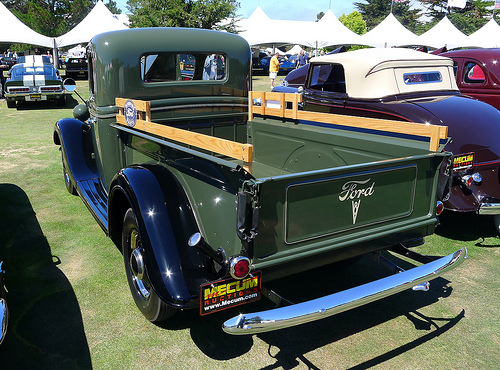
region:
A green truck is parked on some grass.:
[47, 18, 477, 360]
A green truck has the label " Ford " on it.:
[312, 161, 392, 232]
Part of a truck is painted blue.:
[40, 107, 230, 332]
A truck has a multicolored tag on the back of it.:
[186, 265, 266, 323]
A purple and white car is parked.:
[260, 35, 499, 241]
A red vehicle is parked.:
[427, 40, 498, 125]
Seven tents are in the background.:
[0, 0, 499, 92]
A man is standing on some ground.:
[257, 41, 282, 91]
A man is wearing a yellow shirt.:
[261, 47, 286, 77]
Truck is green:
[44, 18, 469, 356]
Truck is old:
[46, 16, 471, 349]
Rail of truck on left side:
[110, 93, 260, 171]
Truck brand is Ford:
[210, 110, 471, 271]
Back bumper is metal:
[190, 240, 471, 350]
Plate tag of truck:
[190, 270, 270, 320]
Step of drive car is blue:
[60, 165, 120, 240]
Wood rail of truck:
[237, 81, 452, 153]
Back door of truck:
[230, 145, 453, 261]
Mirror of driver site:
[33, 29, 84, 112]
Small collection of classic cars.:
[3, 22, 499, 269]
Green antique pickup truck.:
[42, 35, 457, 345]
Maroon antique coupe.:
[288, 40, 498, 220]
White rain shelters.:
[73, 4, 497, 65]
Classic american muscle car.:
[1, 52, 71, 112]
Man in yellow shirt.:
[261, 45, 283, 100]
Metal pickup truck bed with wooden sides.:
[98, 87, 460, 268]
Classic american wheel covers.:
[48, 116, 210, 328]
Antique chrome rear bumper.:
[218, 227, 471, 362]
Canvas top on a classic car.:
[301, 45, 464, 109]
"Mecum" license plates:
[184, 254, 265, 316]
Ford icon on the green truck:
[335, 172, 379, 236]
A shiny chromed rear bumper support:
[217, 240, 469, 342]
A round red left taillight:
[225, 251, 255, 282]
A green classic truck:
[40, 31, 456, 345]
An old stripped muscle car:
[0, 48, 79, 117]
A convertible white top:
[302, 48, 469, 103]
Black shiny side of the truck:
[45, 115, 223, 314]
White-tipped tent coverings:
[7, 5, 496, 57]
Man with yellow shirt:
[266, 47, 288, 87]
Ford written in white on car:
[330, 172, 382, 235]